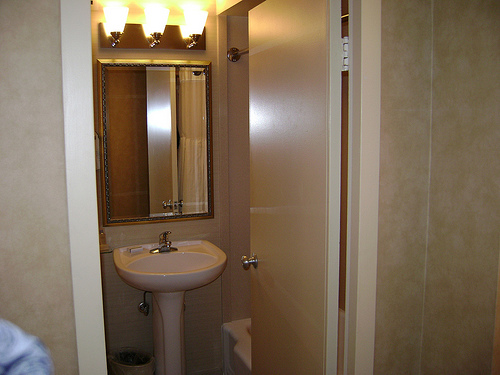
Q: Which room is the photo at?
A: It is at the bathroom.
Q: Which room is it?
A: It is a bathroom.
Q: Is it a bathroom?
A: Yes, it is a bathroom.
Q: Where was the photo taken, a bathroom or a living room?
A: It was taken at a bathroom.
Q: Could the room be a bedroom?
A: No, it is a bathroom.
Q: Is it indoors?
A: Yes, it is indoors.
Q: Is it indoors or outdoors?
A: It is indoors.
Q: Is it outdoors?
A: No, it is indoors.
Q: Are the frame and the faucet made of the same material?
A: No, the frame is made of wood and the faucet is made of metal.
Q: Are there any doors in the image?
A: Yes, there is a door.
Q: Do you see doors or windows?
A: Yes, there is a door.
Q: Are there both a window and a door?
A: No, there is a door but no windows.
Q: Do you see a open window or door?
A: Yes, there is an open door.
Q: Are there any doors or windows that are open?
A: Yes, the door is open.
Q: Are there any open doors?
A: Yes, there is an open door.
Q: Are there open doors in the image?
A: Yes, there is an open door.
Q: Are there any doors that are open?
A: Yes, there is a door that is open.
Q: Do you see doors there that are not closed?
A: Yes, there is a open door.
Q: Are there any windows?
A: No, there are no windows.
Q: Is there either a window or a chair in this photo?
A: No, there are no windows or chairs.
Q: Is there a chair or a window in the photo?
A: No, there are no windows or chairs.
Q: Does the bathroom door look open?
A: Yes, the door is open.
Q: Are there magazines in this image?
A: No, there are no magazines.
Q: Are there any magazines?
A: No, there are no magazines.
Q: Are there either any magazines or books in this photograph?
A: No, there are no magazines or books.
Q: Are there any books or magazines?
A: No, there are no magazines or books.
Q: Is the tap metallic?
A: Yes, the tap is metallic.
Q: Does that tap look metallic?
A: Yes, the tap is metallic.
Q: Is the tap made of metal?
A: Yes, the tap is made of metal.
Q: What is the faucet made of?
A: The tap is made of metal.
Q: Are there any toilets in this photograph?
A: No, there are no toilets.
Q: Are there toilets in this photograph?
A: No, there are no toilets.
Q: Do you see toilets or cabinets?
A: No, there are no toilets or cabinets.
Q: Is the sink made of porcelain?
A: Yes, the sink is made of porcelain.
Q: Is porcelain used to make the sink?
A: Yes, the sink is made of porcelain.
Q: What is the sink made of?
A: The sink is made of porcelain.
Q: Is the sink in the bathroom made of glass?
A: No, the sink is made of porcelain.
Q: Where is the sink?
A: The sink is in the bathroom.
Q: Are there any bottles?
A: No, there are no bottles.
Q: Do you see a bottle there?
A: No, there are no bottles.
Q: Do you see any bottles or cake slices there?
A: No, there are no bottles or cake slices.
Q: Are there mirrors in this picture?
A: Yes, there is a mirror.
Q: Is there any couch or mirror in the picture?
A: Yes, there is a mirror.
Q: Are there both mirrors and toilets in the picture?
A: No, there is a mirror but no toilets.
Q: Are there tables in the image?
A: No, there are no tables.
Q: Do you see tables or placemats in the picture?
A: No, there are no tables or placemats.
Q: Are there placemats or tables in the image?
A: No, there are no tables or placemats.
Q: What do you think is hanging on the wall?
A: The mirror is hanging on the wall.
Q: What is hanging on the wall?
A: The mirror is hanging on the wall.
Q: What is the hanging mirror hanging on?
A: The mirror is hanging on the wall.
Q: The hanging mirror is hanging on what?
A: The mirror is hanging on the wall.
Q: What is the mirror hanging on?
A: The mirror is hanging on the wall.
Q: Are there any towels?
A: No, there are no towels.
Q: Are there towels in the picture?
A: No, there are no towels.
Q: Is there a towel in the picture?
A: No, there are no towels.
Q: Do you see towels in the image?
A: No, there are no towels.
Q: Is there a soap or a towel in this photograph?
A: No, there are no towels or soaps.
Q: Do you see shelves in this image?
A: No, there are no shelves.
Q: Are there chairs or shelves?
A: No, there are no shelves or chairs.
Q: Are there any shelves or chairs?
A: No, there are no shelves or chairs.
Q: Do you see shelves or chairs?
A: No, there are no shelves or chairs.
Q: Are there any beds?
A: No, there are no beds.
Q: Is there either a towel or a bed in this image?
A: No, there are no beds or towels.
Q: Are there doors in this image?
A: Yes, there is a door.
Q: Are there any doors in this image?
A: Yes, there is a door.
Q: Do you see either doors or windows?
A: Yes, there is a door.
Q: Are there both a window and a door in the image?
A: No, there is a door but no windows.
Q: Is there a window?
A: No, there are no windows.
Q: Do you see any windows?
A: No, there are no windows.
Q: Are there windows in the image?
A: No, there are no windows.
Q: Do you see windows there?
A: No, there are no windows.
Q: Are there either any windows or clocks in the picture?
A: No, there are no windows or clocks.